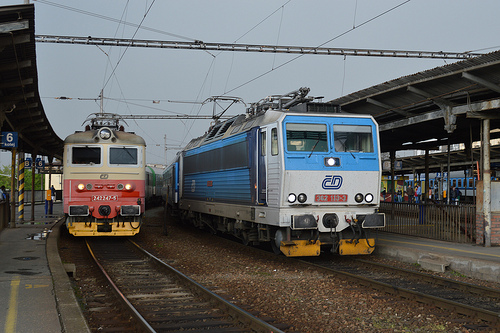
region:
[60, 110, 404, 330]
Two trains approaching a train station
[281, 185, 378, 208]
Lit head lights on train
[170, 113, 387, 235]
Blue and silver train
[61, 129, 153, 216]
Red and beige train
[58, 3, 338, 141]
Electrical wires conected to train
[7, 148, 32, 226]
Black and yellow pole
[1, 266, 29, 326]
Yellow barrier line on train platform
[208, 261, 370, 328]
Brown gravel between tracks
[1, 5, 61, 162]
Roof over train platform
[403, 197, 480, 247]
Metal railing near stairwell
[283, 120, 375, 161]
Front windshield of a blue train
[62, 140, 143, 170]
Front windshield of a red train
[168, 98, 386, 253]
A blue train on the tracks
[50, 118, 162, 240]
A red train on the tracks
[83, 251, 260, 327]
A railroad track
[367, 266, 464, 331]
A railroad track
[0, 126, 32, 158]
Train platform number six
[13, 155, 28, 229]
A black and yellow pillar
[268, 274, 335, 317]
Gravel and river rock between train tracks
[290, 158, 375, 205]
Headlights on a blue train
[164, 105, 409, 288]
train is blue and white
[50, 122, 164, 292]
train is red and white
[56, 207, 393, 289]
front bottom of train is yellow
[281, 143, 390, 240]
lights on front are on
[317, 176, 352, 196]
blue lettering on front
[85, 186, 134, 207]
white numbers on front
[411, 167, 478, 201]
train in the background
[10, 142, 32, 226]
the pole is striped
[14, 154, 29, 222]
the pole is black and yellow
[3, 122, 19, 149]
the sign is blue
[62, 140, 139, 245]
red and white train in station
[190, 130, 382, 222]
blue and white train in station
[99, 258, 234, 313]
gray and brown train tracks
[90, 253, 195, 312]
gray and brown train tracks in station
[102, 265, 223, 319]
gray and brown train tracks in train station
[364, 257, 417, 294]
gray and brown train tracks in train station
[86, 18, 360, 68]
black wires at train station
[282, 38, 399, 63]
black wires at train station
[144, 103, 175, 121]
black wires at train station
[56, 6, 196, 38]
black wires at train station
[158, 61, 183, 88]
A clear overcast sky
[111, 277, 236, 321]
A pair of train tracks on the left side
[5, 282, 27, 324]
Solid yellow line in the train station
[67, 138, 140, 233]
Front of the white and red train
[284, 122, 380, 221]
Front of the blue and white train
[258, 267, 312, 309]
Dirt that are between two tracks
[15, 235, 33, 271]
Sidewalk on train track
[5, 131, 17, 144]
Blue sign that indicates 6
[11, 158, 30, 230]
Yellow and blue pole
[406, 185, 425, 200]
A couple of pedestrians in the background